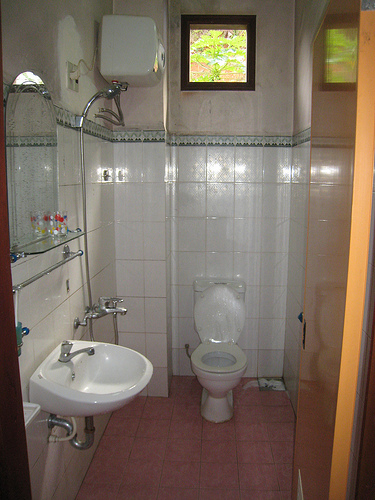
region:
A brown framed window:
[175, 11, 281, 112]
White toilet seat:
[193, 278, 258, 431]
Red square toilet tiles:
[155, 415, 263, 480]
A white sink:
[41, 342, 155, 431]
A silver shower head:
[77, 85, 123, 132]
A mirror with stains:
[9, 65, 102, 272]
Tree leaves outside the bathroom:
[174, 13, 294, 110]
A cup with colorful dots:
[43, 190, 95, 280]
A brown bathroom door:
[275, 184, 367, 479]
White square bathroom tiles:
[94, 171, 302, 288]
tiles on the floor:
[149, 447, 232, 486]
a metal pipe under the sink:
[58, 416, 98, 447]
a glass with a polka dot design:
[49, 207, 74, 238]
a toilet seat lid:
[198, 290, 248, 345]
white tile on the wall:
[194, 193, 242, 250]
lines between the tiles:
[173, 454, 253, 499]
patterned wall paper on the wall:
[170, 131, 290, 153]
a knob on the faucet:
[53, 338, 78, 354]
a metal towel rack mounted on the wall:
[18, 254, 102, 288]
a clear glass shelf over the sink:
[21, 237, 90, 257]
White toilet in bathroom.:
[185, 272, 254, 426]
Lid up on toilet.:
[191, 283, 249, 343]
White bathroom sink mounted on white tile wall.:
[25, 336, 156, 413]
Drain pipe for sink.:
[46, 416, 111, 454]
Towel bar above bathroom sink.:
[9, 242, 83, 296]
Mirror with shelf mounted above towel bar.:
[6, 82, 107, 259]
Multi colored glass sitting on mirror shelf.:
[45, 207, 71, 243]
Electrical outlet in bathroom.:
[56, 52, 86, 103]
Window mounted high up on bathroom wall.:
[176, 9, 266, 94]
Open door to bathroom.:
[290, 8, 373, 499]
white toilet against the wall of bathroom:
[187, 277, 262, 425]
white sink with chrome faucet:
[34, 338, 158, 419]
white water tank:
[96, 6, 177, 94]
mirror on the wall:
[13, 78, 75, 250]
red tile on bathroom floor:
[160, 414, 238, 498]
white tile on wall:
[126, 177, 166, 264]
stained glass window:
[183, 21, 254, 93]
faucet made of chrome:
[77, 298, 146, 331]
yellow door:
[300, 210, 368, 488]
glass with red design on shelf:
[47, 209, 82, 243]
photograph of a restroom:
[5, 4, 365, 495]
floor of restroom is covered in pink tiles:
[111, 410, 286, 486]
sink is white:
[35, 334, 152, 424]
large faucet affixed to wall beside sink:
[67, 285, 135, 362]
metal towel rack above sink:
[11, 248, 105, 364]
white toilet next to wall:
[166, 255, 249, 420]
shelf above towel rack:
[16, 225, 85, 279]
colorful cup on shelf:
[47, 207, 73, 245]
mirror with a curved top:
[3, 65, 69, 239]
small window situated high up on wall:
[171, 5, 287, 307]